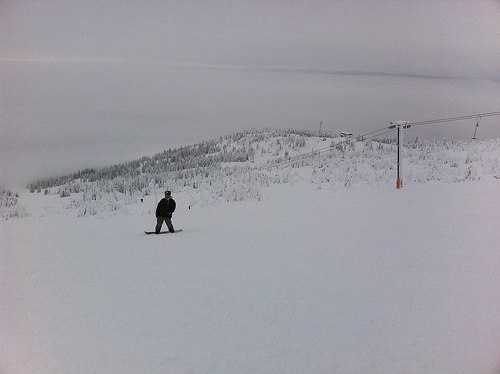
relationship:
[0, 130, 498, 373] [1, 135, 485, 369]
snow on ground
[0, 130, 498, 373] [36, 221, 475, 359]
snow on ground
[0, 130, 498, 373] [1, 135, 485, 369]
snow covering ground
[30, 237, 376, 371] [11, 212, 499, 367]
path through snow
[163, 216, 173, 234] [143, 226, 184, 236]
leg on board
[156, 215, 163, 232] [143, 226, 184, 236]
leg on board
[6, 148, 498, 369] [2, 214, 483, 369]
snow on ground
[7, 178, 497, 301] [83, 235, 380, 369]
slope covered in snow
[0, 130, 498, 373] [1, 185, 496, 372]
snow on ground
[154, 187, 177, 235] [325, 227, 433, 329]
snowboarder in snow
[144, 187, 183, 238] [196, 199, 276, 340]
snowboarder on slope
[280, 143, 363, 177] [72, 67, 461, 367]
stubble in snow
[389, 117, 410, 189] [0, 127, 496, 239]
pole on top of slope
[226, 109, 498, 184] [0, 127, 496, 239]
wires on top of slope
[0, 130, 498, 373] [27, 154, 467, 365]
snow on ground